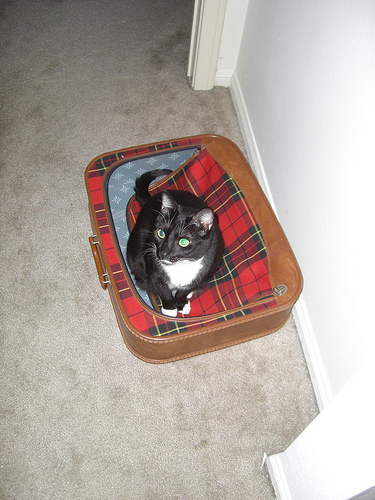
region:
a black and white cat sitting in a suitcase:
[78, 130, 302, 365]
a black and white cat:
[124, 167, 225, 317]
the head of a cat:
[148, 191, 218, 268]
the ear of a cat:
[192, 205, 215, 237]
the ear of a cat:
[159, 187, 177, 211]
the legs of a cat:
[156, 282, 198, 321]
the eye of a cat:
[155, 227, 166, 239]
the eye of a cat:
[176, 234, 192, 248]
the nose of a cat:
[157, 248, 170, 258]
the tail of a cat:
[130, 166, 171, 200]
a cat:
[130, 188, 221, 305]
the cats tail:
[131, 174, 153, 199]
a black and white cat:
[125, 180, 234, 313]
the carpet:
[17, 333, 115, 487]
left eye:
[177, 237, 190, 248]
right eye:
[158, 227, 167, 240]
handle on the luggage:
[84, 239, 109, 287]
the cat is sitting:
[116, 183, 244, 319]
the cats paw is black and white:
[160, 300, 178, 318]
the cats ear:
[195, 206, 216, 229]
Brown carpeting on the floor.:
[0, 0, 319, 498]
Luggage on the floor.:
[77, 128, 302, 361]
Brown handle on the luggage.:
[84, 228, 106, 288]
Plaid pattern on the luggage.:
[82, 135, 272, 335]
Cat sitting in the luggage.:
[122, 165, 220, 315]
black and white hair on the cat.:
[123, 165, 217, 315]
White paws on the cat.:
[157, 297, 188, 313]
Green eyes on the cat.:
[152, 223, 190, 247]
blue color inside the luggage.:
[107, 146, 161, 308]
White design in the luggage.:
[110, 169, 126, 181]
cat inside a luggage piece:
[105, 161, 221, 295]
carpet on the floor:
[5, 18, 221, 494]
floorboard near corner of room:
[262, 447, 298, 498]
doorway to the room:
[2, 3, 189, 79]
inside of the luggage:
[114, 170, 134, 213]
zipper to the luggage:
[184, 145, 207, 156]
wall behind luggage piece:
[261, 68, 357, 184]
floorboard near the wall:
[290, 318, 333, 393]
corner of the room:
[225, 24, 240, 91]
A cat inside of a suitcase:
[83, 133, 307, 366]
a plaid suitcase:
[84, 131, 304, 364]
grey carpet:
[0, 1, 325, 498]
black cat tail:
[133, 168, 175, 207]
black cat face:
[150, 191, 217, 264]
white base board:
[213, 67, 334, 413]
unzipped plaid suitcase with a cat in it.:
[82, 131, 303, 365]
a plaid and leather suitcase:
[85, 131, 304, 364]